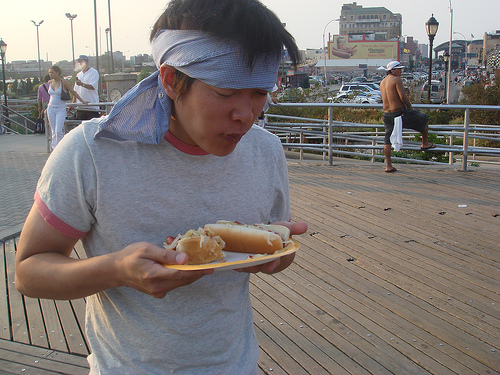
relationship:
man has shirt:
[16, 2, 304, 371] [84, 130, 198, 197]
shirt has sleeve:
[84, 130, 198, 197] [34, 145, 96, 226]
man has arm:
[16, 2, 304, 371] [26, 245, 159, 298]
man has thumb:
[16, 2, 304, 371] [147, 248, 176, 262]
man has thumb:
[16, 2, 304, 371] [288, 220, 308, 231]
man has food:
[16, 2, 304, 371] [164, 220, 300, 271]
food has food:
[164, 220, 300, 271] [187, 230, 254, 247]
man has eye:
[16, 2, 304, 371] [213, 89, 239, 102]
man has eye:
[16, 2, 304, 371] [257, 90, 270, 100]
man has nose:
[16, 2, 304, 371] [236, 104, 256, 128]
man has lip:
[16, 2, 304, 371] [229, 131, 249, 137]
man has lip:
[16, 2, 304, 371] [225, 138, 235, 144]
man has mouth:
[16, 2, 304, 371] [218, 129, 247, 144]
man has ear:
[16, 2, 304, 371] [160, 64, 174, 97]